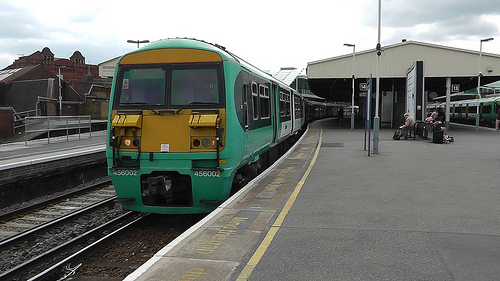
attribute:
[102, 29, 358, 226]
train — green, yellow, white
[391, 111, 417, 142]
person — waiting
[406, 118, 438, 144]
bench — black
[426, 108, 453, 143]
person — waiting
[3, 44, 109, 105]
building — red, brick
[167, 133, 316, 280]
letters — yellow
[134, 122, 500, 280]
cement — gray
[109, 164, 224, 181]
letters — white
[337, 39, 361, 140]
street light — tall, white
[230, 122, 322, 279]
line — long, yellow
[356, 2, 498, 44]
cloud — gray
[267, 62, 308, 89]
structure — small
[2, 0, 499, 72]
sky — filled